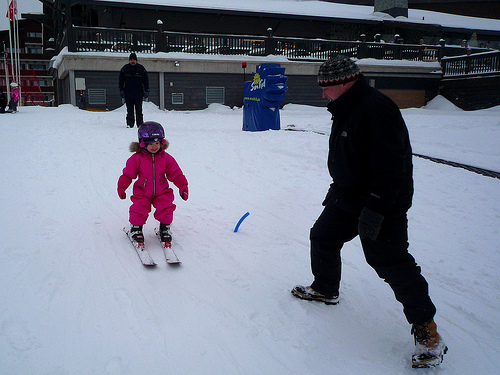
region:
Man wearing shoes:
[290, 276, 452, 369]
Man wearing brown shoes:
[288, 271, 450, 371]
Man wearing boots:
[290, 277, 454, 370]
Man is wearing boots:
[283, 276, 453, 367]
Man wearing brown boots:
[288, 271, 449, 367]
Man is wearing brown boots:
[291, 277, 450, 372]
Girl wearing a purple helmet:
[135, 115, 167, 142]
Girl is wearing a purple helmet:
[132, 116, 169, 143]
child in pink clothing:
[95, 122, 206, 254]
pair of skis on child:
[106, 219, 191, 279]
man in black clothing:
[106, 48, 159, 123]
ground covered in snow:
[6, 129, 113, 229]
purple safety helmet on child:
[130, 122, 178, 143]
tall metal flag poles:
[0, 0, 30, 108]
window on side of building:
[196, 80, 230, 105]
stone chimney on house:
[371, 0, 414, 16]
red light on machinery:
[234, 53, 253, 85]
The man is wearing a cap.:
[107, 45, 158, 132]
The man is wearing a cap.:
[290, 50, 451, 367]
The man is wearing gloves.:
[111, 50, 159, 134]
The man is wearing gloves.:
[287, 53, 459, 371]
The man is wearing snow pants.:
[111, 48, 156, 131]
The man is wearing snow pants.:
[274, 50, 456, 370]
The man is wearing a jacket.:
[113, 46, 156, 133]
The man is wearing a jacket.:
[291, 43, 460, 373]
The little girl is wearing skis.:
[102, 101, 200, 276]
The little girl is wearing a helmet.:
[100, 110, 195, 283]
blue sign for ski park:
[240, 64, 285, 134]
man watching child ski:
[295, 50, 447, 362]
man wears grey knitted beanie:
[316, 55, 361, 82]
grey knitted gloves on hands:
[355, 210, 387, 239]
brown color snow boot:
[290, 285, 342, 304]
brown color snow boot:
[411, 320, 443, 367]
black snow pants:
[370, 241, 437, 325]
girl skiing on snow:
[119, 121, 184, 268]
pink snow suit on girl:
[129, 150, 179, 224]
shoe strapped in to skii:
[159, 225, 171, 243]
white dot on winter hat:
[321, 60, 326, 67]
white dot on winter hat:
[327, 60, 335, 69]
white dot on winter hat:
[333, 57, 345, 67]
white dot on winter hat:
[341, 55, 350, 65]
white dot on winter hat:
[346, 61, 355, 71]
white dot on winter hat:
[337, 65, 345, 73]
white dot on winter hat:
[316, 68, 325, 78]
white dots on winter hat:
[318, 62, 354, 77]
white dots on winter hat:
[318, 53, 346, 70]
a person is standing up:
[111, 117, 197, 257]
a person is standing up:
[288, 57, 451, 372]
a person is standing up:
[115, 50, 154, 128]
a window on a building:
[28, 30, 35, 42]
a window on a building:
[33, 31, 43, 41]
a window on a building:
[22, 42, 32, 56]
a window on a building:
[31, 42, 34, 53]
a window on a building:
[34, 43, 45, 56]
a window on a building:
[21, 56, 30, 69]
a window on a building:
[23, 75, 30, 87]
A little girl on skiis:
[115, 120, 192, 272]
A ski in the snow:
[122, 223, 157, 269]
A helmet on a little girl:
[137, 121, 166, 143]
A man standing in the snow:
[288, 53, 450, 370]